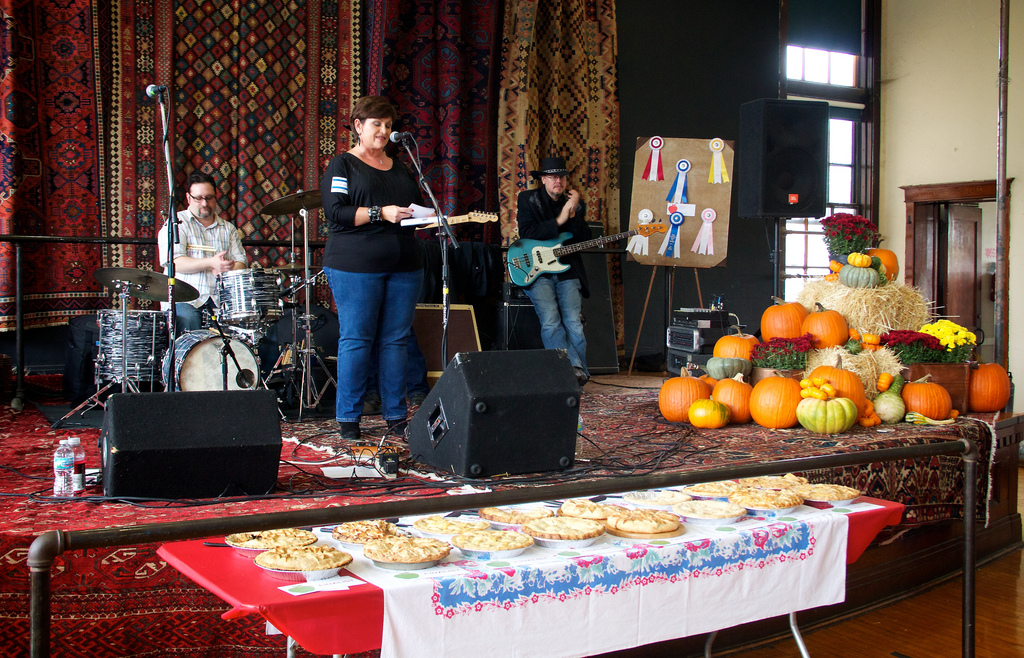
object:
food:
[607, 509, 683, 533]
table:
[154, 475, 905, 658]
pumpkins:
[800, 300, 849, 349]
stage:
[0, 373, 1024, 658]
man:
[158, 170, 248, 338]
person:
[506, 156, 593, 386]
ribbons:
[641, 135, 665, 181]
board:
[624, 136, 733, 269]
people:
[321, 95, 441, 439]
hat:
[529, 156, 579, 180]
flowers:
[844, 235, 850, 241]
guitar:
[507, 219, 668, 287]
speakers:
[737, 98, 827, 219]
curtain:
[0, 0, 622, 389]